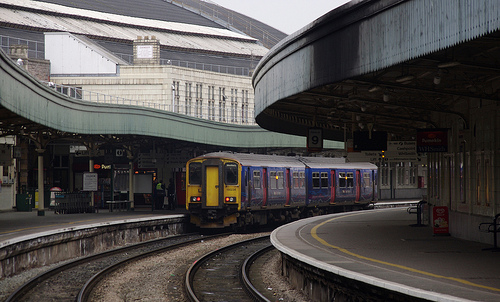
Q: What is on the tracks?
A: Train.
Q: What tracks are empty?
A: Right one.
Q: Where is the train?
A: At station.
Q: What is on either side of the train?
A: Platform.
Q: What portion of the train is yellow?
A: Front.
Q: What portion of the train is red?
A: Doors.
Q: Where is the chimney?
A: Brick building beyond the station.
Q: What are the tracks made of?
A: Metal.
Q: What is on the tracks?
A: Train.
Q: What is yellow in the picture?
A: A train.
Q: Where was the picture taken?
A: Train station.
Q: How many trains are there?
A: One.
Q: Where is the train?
A: On the tracks.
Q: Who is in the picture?
A: No one.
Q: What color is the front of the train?
A: Yellow.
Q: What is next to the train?
A: Platform.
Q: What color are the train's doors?
A: Red.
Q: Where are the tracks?
A: On the ground.